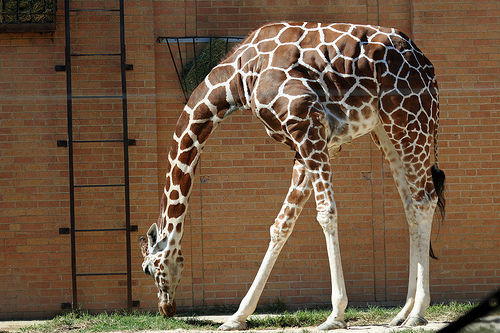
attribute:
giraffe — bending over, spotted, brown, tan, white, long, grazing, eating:
[138, 18, 448, 328]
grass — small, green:
[19, 311, 219, 330]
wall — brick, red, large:
[1, 0, 499, 317]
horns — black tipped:
[139, 236, 150, 259]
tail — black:
[430, 129, 446, 221]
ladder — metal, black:
[55, 0, 139, 316]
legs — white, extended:
[217, 159, 351, 331]